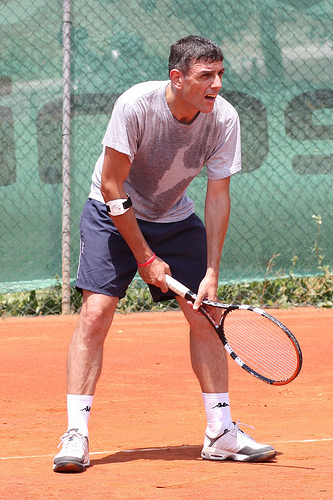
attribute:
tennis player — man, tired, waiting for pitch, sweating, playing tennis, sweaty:
[53, 30, 277, 476]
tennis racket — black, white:
[154, 271, 305, 390]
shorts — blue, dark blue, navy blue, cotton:
[76, 197, 216, 304]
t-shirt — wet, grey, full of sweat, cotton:
[90, 81, 243, 224]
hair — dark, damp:
[166, 36, 221, 76]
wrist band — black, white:
[102, 191, 133, 220]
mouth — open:
[203, 90, 216, 103]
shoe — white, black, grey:
[54, 427, 94, 476]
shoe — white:
[203, 428, 279, 466]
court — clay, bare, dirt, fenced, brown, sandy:
[1, 306, 326, 500]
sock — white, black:
[65, 393, 93, 437]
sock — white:
[203, 390, 235, 436]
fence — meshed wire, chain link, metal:
[1, 0, 331, 308]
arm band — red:
[137, 252, 160, 269]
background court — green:
[3, 1, 328, 296]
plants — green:
[2, 274, 332, 311]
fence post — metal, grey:
[58, 2, 79, 314]